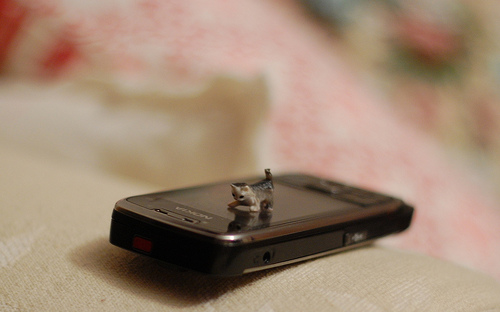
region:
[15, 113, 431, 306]
a cell phone on the arm of a chair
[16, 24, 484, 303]
cell phone sitting on a chair arm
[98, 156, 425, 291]
a black and silver phone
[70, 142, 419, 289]
a cell phone with a tiny cat on top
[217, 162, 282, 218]
a tiny ceramic cat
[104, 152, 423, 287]
a mobile phone with a cat on it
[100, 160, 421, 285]
a mobile phone on a chair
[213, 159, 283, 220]
an itty bitty kitten on a cell phone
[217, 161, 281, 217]
a miniature kitten sitting on a phone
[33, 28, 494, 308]
a phone and a kitten on a chair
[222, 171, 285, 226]
small figurine of a grey cat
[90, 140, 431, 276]
toy cat on a cell phone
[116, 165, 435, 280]
black mobile phone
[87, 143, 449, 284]
black phone with a cat figurine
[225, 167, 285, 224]
tiny gray cat figurine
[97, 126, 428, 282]
black cell phone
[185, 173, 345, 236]
toy cat sitting on a phone screen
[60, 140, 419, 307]
cellular phone with toy on screen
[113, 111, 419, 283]
all black phone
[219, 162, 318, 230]
toy of a kitten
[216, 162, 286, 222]
cat figurine on top of the phone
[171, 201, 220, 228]
Nokia logo on the phone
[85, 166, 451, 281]
candy bar phone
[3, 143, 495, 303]
phone rests on cream-colored arm rest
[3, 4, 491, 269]
background is blurry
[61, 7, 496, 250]
red and white blanket in the background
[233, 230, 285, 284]
hole on the side for headphones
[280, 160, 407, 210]
button as bottom of the phone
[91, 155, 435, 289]
phone is brown and black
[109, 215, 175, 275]
red light at top of the phone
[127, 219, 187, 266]
a red button on the phone.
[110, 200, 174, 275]
a red button on the phone.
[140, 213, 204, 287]
a red button on the phone.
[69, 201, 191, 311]
a red button on the phone.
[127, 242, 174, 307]
a red button on the phone.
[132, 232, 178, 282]
a red button on the phone.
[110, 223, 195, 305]
a red button on the phone.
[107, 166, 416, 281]
The cell phone in the photo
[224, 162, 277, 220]
The cat on the cell phone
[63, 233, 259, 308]
The shadow of the cell phone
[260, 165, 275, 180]
The tail of the cat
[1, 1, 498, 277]
The pink blanket in the background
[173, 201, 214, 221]
The name of the company on the phone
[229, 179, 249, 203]
The head of the cat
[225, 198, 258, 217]
The front legs of the cat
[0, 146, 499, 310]
The tan arm of the chair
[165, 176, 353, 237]
The screen on the phone